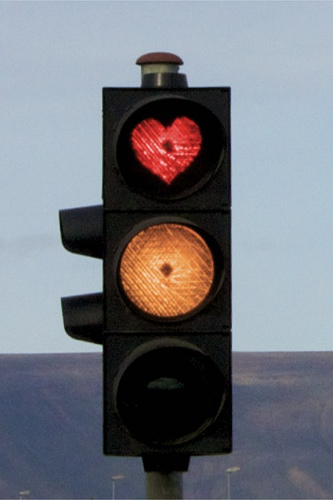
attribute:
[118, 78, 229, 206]
light — visable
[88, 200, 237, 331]
light — visable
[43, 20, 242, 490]
light — black, traffic, double-sided, street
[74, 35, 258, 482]
light — traffic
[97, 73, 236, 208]
color — three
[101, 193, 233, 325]
color — three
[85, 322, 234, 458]
color — three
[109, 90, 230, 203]
color — red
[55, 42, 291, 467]
light — traffic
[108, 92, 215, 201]
shape — heart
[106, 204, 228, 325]
light — round, orange, red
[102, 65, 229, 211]
light — red, traffic, bright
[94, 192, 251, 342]
light — orange, traffic, bright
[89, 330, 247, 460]
light — green, turned-off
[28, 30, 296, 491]
light — traffic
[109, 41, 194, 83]
top — red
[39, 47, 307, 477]
light — traffic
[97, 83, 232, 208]
circle — black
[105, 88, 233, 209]
light — red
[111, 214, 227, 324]
circle — orange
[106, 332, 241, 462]
circle — black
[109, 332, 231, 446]
light — green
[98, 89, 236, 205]
light — traffic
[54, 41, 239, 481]
light — traffic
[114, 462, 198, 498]
post — metal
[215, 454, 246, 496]
light — street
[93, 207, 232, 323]
light — yellow, traffic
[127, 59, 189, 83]
post — metal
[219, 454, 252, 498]
light — three, street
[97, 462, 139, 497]
light — three, street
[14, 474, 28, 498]
light — three, street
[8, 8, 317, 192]
sky — clear, blue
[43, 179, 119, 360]
lights — street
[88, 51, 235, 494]
light — street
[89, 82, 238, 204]
light — red, on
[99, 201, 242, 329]
light — yellow, on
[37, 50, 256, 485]
light — traffic, black